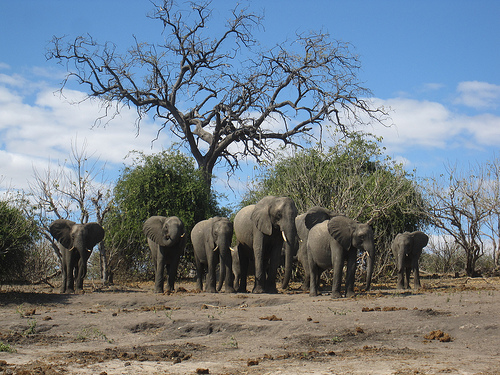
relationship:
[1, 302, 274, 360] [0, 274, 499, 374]
hills in dirt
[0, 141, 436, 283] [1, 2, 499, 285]
trees in background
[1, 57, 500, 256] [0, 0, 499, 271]
clouds in sky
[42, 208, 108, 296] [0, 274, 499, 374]
elephant in field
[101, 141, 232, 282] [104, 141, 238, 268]
tree has leaves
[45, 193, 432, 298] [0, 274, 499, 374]
elephants in field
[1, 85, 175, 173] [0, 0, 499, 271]
cloud in sky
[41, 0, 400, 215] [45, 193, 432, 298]
tree behind elephants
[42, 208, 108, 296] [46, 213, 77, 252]
elephant has ear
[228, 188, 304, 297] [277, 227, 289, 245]
elephant has tusk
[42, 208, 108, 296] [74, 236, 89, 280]
elephant has nose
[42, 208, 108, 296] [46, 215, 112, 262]
elephant has head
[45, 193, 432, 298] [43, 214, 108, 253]
elephants has ears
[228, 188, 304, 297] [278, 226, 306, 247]
elephant has tusks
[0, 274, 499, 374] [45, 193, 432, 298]
ground under elephants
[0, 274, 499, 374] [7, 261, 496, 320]
dirt on ground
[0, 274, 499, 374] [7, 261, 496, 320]
ground on ground